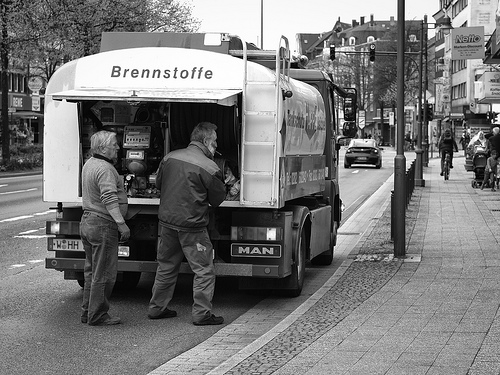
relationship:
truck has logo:
[43, 41, 359, 299] [109, 63, 214, 81]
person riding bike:
[439, 122, 460, 176] [440, 142, 462, 182]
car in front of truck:
[343, 136, 384, 171] [43, 41, 359, 299]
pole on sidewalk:
[393, 1, 406, 260] [204, 147, 499, 373]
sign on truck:
[230, 243, 284, 257] [43, 41, 359, 299]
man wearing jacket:
[148, 122, 230, 325] [153, 142, 226, 229]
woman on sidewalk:
[467, 131, 494, 164] [204, 147, 499, 373]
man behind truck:
[148, 122, 230, 325] [43, 41, 359, 299]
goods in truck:
[80, 100, 238, 199] [43, 41, 359, 299]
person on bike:
[439, 122, 460, 176] [440, 142, 462, 182]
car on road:
[343, 136, 384, 171] [0, 144, 397, 374]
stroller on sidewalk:
[470, 151, 490, 189] [204, 147, 499, 373]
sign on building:
[448, 25, 487, 61] [483, 6, 500, 74]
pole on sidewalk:
[411, 18, 428, 188] [204, 147, 499, 373]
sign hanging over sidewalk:
[448, 25, 487, 61] [204, 147, 499, 373]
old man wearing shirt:
[81, 128, 133, 327] [77, 157, 131, 225]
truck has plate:
[43, 41, 359, 299] [47, 236, 88, 255]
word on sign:
[237, 244, 273, 255] [230, 243, 284, 257]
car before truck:
[343, 136, 384, 171] [43, 41, 359, 299]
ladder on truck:
[240, 34, 292, 205] [43, 41, 359, 299]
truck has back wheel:
[43, 41, 359, 299] [270, 225, 309, 299]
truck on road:
[43, 41, 359, 299] [0, 144, 397, 374]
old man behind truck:
[81, 128, 133, 327] [43, 41, 359, 299]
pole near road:
[411, 18, 428, 188] [0, 144, 397, 374]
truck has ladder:
[43, 41, 359, 299] [240, 34, 292, 205]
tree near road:
[3, 1, 200, 59] [0, 144, 397, 374]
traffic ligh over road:
[365, 41, 377, 62] [0, 144, 397, 374]